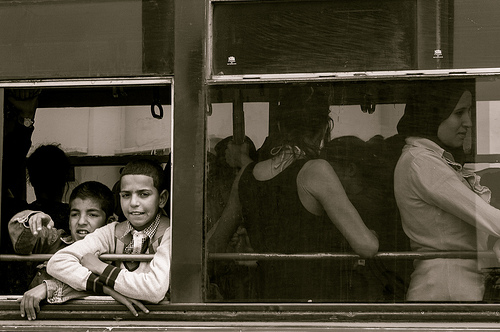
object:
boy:
[47, 162, 173, 317]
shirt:
[111, 214, 162, 273]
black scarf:
[396, 76, 477, 148]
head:
[395, 80, 472, 149]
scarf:
[403, 134, 473, 157]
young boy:
[46, 214, 170, 317]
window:
[0, 0, 174, 86]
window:
[210, 0, 498, 76]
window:
[204, 84, 500, 302]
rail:
[205, 251, 500, 260]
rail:
[0, 250, 169, 263]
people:
[22, 142, 74, 289]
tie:
[269, 137, 302, 172]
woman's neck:
[270, 143, 310, 156]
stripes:
[85, 272, 105, 293]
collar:
[114, 212, 161, 255]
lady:
[206, 83, 378, 303]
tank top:
[235, 150, 326, 299]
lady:
[392, 77, 500, 252]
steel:
[207, 249, 497, 260]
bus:
[0, 0, 497, 332]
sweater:
[46, 214, 173, 303]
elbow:
[351, 232, 380, 259]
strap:
[149, 102, 164, 120]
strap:
[356, 99, 368, 112]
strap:
[367, 100, 375, 115]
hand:
[28, 213, 54, 238]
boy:
[7, 181, 119, 322]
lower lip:
[130, 214, 146, 218]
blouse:
[393, 136, 500, 250]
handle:
[150, 99, 164, 120]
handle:
[360, 90, 376, 114]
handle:
[206, 101, 213, 116]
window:
[2, 77, 171, 304]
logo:
[226, 55, 237, 66]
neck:
[270, 136, 311, 158]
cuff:
[85, 263, 122, 295]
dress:
[236, 158, 352, 302]